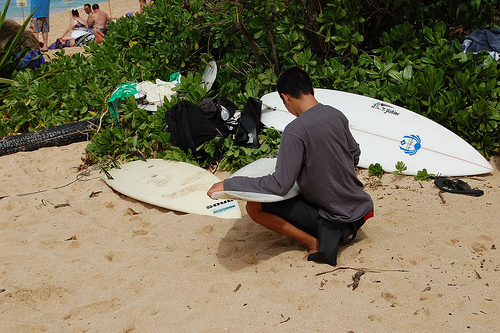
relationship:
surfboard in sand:
[100, 157, 244, 219] [85, 215, 205, 332]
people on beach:
[56, 4, 110, 48] [14, 18, 70, 47]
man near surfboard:
[208, 68, 373, 263] [100, 157, 244, 219]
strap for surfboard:
[433, 176, 487, 198] [260, 89, 497, 179]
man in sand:
[208, 68, 373, 263] [85, 215, 205, 332]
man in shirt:
[208, 68, 373, 263] [223, 105, 374, 221]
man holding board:
[208, 68, 373, 263] [212, 157, 301, 203]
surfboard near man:
[260, 89, 497, 179] [208, 68, 373, 263]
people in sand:
[56, 4, 110, 48] [85, 215, 205, 332]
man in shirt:
[29, 2, 51, 53] [30, 0, 51, 17]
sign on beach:
[15, 1, 30, 23] [14, 18, 70, 47]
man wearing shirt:
[208, 68, 373, 263] [223, 105, 374, 221]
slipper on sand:
[435, 177, 486, 197] [85, 215, 205, 332]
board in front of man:
[212, 157, 301, 203] [208, 68, 373, 263]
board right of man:
[212, 157, 301, 203] [208, 68, 373, 263]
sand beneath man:
[85, 215, 205, 332] [208, 68, 373, 263]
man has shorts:
[29, 2, 51, 53] [30, 13, 51, 33]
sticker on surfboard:
[399, 132, 422, 157] [260, 89, 497, 179]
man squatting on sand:
[208, 68, 373, 263] [85, 215, 205, 332]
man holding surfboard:
[208, 68, 373, 263] [100, 157, 244, 219]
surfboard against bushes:
[260, 89, 497, 179] [158, 2, 500, 137]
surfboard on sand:
[100, 157, 244, 219] [85, 215, 205, 332]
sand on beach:
[85, 215, 205, 332] [14, 18, 70, 47]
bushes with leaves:
[158, 2, 500, 137] [333, 27, 364, 57]